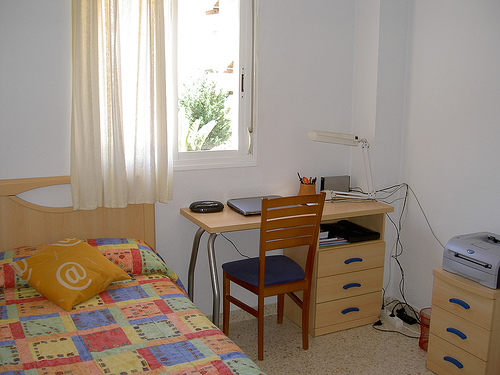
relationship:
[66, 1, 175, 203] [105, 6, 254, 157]
white curtain on window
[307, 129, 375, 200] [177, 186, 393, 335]
lamp on desk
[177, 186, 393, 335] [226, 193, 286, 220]
desk has a laptop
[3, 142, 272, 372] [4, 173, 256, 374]
bedroom has bed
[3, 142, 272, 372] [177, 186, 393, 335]
bedroom has desk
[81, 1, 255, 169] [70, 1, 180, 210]
window has white curtain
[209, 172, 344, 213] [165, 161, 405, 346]
computer on desk